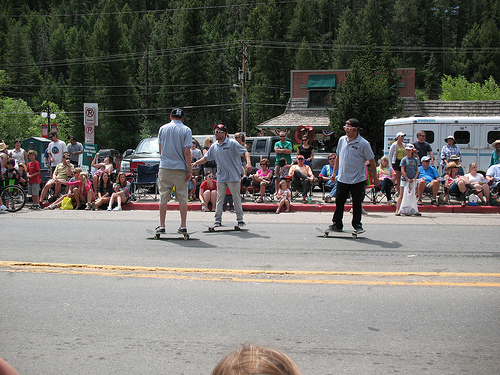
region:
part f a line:
[351, 258, 385, 294]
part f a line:
[361, 268, 382, 287]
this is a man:
[321, 109, 385, 251]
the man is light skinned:
[346, 126, 351, 136]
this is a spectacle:
[340, 126, 356, 133]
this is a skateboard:
[321, 222, 364, 242]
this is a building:
[288, 62, 373, 122]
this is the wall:
[293, 71, 303, 92]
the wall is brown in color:
[293, 79, 305, 96]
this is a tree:
[348, 62, 385, 115]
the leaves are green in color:
[348, 79, 380, 126]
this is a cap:
[163, 107, 188, 117]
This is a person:
[136, 98, 204, 240]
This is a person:
[194, 118, 262, 238]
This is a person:
[309, 113, 390, 243]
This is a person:
[411, 128, 451, 218]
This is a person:
[260, 124, 300, 184]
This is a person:
[290, 152, 329, 205]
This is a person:
[12, 146, 48, 206]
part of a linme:
[345, 250, 357, 280]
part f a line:
[363, 250, 384, 284]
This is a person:
[325, 110, 382, 243]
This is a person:
[148, 99, 197, 254]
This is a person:
[190, 122, 254, 238]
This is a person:
[249, 151, 273, 199]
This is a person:
[272, 171, 294, 218]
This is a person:
[286, 152, 321, 204]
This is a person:
[273, 122, 293, 179]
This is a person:
[296, 116, 322, 167]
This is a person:
[108, 162, 136, 217]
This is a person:
[43, 122, 70, 179]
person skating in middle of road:
[145, 109, 203, 241]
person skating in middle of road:
[189, 121, 256, 235]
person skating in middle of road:
[322, 118, 376, 235]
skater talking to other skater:
[192, 126, 252, 230]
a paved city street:
[1, 203, 498, 374]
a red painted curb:
[37, 200, 497, 214]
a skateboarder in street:
[314, 118, 381, 238]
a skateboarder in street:
[194, 123, 252, 233]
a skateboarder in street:
[147, 106, 198, 242]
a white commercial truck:
[382, 115, 498, 185]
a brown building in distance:
[257, 68, 499, 161]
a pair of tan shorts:
[155, 167, 191, 205]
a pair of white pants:
[212, 178, 244, 223]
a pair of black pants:
[330, 178, 367, 225]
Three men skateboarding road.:
[144, 104, 384, 246]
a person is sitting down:
[63, 170, 78, 200]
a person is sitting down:
[82, 162, 111, 211]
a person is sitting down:
[101, 171, 126, 213]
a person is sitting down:
[91, 150, 110, 174]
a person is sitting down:
[195, 167, 217, 214]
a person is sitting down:
[272, 174, 288, 216]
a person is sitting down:
[288, 155, 313, 200]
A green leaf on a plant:
[153, 22, 157, 23]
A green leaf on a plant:
[108, 19, 113, 22]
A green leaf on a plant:
[255, 25, 259, 27]